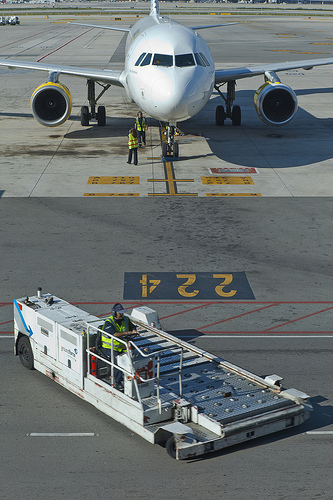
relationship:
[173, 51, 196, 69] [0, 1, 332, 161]
window on front of airplane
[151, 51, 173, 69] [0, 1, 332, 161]
window on front of airplane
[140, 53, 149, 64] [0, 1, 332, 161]
window on front of airplane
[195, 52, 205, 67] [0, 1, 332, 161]
window on front of airplane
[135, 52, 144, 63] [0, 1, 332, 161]
window on front of airplane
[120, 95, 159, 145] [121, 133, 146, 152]
man in vest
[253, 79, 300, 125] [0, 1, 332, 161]
engines on airplane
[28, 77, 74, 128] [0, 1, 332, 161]
engines on airplane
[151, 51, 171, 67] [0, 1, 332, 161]
window on airplane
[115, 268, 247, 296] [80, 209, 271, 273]
numbers on tarmac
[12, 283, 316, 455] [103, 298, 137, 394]
heavy machinery driven by man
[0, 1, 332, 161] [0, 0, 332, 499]
airplane parked on pavement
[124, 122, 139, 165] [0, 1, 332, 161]
person standing under airplane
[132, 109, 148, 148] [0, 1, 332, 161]
man standing under airplane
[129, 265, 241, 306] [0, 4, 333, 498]
224 painted on airport lot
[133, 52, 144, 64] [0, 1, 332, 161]
window of airplane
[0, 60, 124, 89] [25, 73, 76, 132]
wing with engine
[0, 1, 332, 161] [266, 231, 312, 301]
airplane sitting in lot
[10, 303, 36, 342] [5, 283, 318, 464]
arrow painted on side of vehicle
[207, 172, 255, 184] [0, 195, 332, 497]
numbers on ground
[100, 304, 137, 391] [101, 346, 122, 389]
man wearing jeans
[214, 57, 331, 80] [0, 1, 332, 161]
wing of airplane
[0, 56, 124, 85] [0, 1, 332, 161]
wing of airplane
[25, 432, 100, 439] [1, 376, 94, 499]
line on pavement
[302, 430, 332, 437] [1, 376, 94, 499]
line on pavement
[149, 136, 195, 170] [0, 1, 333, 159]
wheel on plane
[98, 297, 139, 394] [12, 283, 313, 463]
man driving heavy machinery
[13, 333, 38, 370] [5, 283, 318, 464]
tire on vehicle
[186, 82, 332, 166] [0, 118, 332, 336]
shadow on ground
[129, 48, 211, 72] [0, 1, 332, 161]
window on airplane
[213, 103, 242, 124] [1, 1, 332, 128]
wheels on airplane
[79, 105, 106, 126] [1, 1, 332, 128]
wheels on airplane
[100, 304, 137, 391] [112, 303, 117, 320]
man wearing earmuffs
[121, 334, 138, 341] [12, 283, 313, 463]
steering wheel on heavy machinery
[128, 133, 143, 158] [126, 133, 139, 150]
person wears vest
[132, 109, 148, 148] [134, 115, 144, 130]
man wears vest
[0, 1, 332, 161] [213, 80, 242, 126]
airplane has landing gear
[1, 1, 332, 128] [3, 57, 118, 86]
airplane has wing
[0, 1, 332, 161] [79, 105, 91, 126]
airplane has wheels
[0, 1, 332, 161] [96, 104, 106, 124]
airplane has tire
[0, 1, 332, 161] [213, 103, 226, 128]
airplane has wheels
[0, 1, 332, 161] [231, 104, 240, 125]
airplane has tire